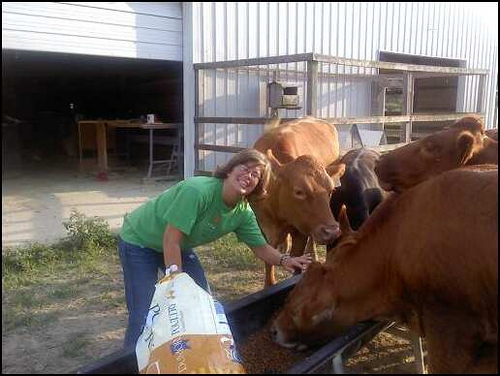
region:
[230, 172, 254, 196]
the lady is smiling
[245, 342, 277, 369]
the feed is brown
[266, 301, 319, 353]
the cow is eating the feed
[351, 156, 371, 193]
the cow is black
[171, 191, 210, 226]
the shirt is green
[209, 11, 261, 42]
the building is white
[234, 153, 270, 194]
the lady is wearing glasses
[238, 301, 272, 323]
the feed bin is black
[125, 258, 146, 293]
the pants are blue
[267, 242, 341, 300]
the lady is reaching out to the cow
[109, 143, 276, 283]
Woman in a green shirt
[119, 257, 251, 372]
Bag of cow feed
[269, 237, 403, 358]
Cow eating out of feed bin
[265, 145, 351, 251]
Brown cow stading on grass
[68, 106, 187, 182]
Table inside of a barn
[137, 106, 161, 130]
Mug on top of table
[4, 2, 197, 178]
White barn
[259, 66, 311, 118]
Bird house on outside of barn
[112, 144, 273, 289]
Woman petting a cow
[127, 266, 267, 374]
Brown and white bag of cow food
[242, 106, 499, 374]
THE COWS ARE EATING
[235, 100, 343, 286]
THE COW IS BROWN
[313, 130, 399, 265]
THE COW IS BLACK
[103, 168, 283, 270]
THE WOMAN IS WEARING A T-SHIRT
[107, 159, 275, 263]
THE WOMAN'S SHIRT IS GREEN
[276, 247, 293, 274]
THE WOMAN IS WEARING A BRACELET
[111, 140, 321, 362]
THE WOMAN IS FEEDING THE COWS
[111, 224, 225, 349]
THE WOMAN IS WEARING BLUE JEANS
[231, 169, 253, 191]
THE WOMAN IS SMILING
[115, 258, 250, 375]
THE BAG IS FILLED WITH COW FEED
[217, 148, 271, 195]
the woman has light brown hair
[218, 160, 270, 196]
the woman is smiling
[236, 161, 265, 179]
the woman is wearing glasses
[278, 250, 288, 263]
the woman is wearing a bracelet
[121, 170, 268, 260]
the woman is wearing a t shirt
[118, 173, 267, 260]
the t shirt is green in color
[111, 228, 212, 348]
the woman is wearing jeans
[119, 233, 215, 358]
the jeans are blue in color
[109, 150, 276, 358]
the woman is bending down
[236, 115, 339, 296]
a cow in next to the woman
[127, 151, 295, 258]
a woman wearing a green shirt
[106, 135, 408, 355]
a woman feeding the cows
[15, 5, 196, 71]
a metal overhead door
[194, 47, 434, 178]
a wooden frame against a building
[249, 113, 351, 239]
a brown cow with a pink nose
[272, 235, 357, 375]
a brown cow eating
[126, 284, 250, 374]
a white and brown bag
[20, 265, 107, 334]
green and brown grass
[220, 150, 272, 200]
a woman wearing glasses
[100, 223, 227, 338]
a woman wearing blue jeans